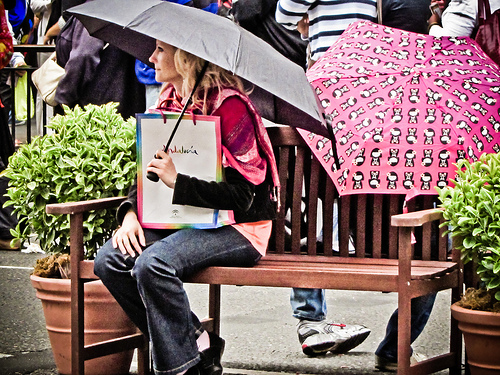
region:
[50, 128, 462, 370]
a wooden bench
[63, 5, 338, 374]
woman with the black umbrella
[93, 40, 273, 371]
woman with blonde hair holding bag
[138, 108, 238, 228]
bag in woman's hand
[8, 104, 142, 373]
plant in a pot on left of bench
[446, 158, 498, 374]
plant in pot on right of bench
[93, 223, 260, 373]
blue jeans on the woman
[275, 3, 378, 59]
person in white shirt with black stripes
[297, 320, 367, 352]
gray tennis shoe under the bench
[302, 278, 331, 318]
edge of a bench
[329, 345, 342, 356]
edge of a sole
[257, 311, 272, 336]
part of a floor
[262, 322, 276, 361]
par tof a floor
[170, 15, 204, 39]
Light on black umbrella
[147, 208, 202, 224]
A paper bag on the lap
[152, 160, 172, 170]
Fingers on the umbrella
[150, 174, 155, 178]
The black umbrella handle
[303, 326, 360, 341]
Shoe under a bench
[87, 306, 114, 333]
A pot with a plant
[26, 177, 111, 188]
A plant in the pot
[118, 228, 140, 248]
Hand on the knee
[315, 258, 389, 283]
A wooden bench on the ground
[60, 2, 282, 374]
This is a person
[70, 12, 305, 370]
This is a person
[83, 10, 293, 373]
This is a person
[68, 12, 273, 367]
This is a person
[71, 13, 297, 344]
This is a person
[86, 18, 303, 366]
This is a person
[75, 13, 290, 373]
This is a person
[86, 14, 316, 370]
This is a person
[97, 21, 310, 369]
This is a person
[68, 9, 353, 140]
black umbrella being held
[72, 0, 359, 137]
top cover of umbrella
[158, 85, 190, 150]
black metal pole of umbrella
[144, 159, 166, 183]
black handle of umbrella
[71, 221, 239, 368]
blue jeans on woman's legs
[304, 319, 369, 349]
grey and black shoes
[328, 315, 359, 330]
red logo on side of shoes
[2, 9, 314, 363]
woman sitting down on bench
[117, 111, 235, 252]
bag in lap of woman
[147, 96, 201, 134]
pink handle of bag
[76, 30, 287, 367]
a woman is sitting down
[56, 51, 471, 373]
woman sitting on a bench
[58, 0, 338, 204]
woman holding a umbrella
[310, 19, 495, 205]
a pink and black umbrella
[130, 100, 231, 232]
woman holding a bag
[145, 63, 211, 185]
handle of the umbrella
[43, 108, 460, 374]
the bench is brown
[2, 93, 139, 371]
potted plant on the side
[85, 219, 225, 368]
a pair of blue jeans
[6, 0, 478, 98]
people in the background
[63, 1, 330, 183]
umbrella held by human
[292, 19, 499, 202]
umbrella held by human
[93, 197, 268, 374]
pants worn by human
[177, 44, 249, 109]
blonde hair is worn long